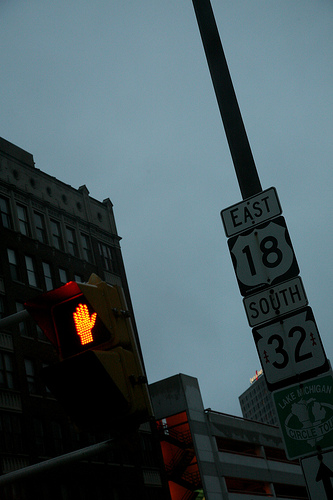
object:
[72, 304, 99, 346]
hand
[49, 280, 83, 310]
reflection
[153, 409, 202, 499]
light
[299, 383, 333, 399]
word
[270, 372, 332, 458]
sign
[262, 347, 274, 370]
arrow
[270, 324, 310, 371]
32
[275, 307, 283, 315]
bolt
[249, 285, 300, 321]
word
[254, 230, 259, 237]
stain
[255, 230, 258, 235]
bolt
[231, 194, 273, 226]
east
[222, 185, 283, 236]
rectangle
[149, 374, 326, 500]
garage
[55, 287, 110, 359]
sign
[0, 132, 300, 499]
building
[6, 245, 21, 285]
window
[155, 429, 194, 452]
stairs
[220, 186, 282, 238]
sign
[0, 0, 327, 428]
distance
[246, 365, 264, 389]
sign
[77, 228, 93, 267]
window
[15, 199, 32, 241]
window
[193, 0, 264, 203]
post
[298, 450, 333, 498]
sign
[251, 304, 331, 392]
sign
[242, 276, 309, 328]
sign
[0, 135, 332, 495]
background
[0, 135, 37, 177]
top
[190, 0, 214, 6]
lamp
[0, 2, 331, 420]
sky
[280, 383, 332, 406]
lake michigan